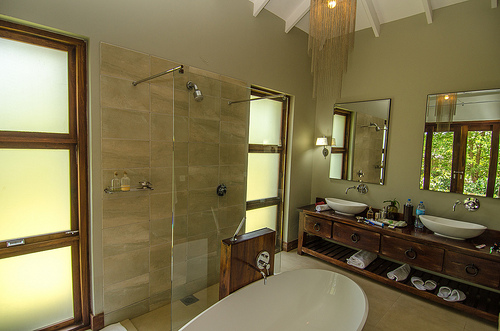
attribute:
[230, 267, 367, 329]
tub — white, porcelain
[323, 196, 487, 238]
sinks — white, bowl shaped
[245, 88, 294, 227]
window — wood, large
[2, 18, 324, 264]
wall — stone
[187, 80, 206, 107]
shower head — silver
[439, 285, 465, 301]
slippers — white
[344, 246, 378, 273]
towels — white, folded, rolled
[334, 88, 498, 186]
mirrors — reflecting, square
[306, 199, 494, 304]
table — brown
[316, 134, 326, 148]
shade — white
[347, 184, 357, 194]
faucet — metal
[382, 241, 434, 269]
drawer — wood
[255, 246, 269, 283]
faucet — metal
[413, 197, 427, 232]
bottle — plastic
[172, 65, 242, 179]
wall — glass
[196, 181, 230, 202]
fixtures — metal